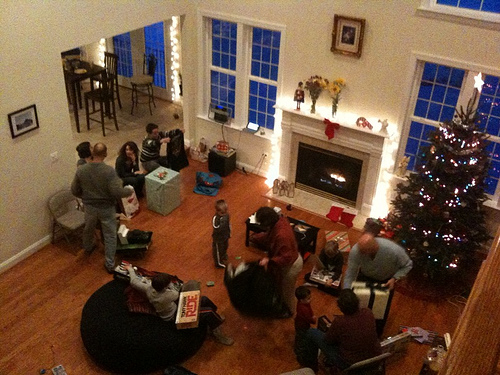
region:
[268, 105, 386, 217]
Fire place with fire lit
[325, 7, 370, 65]
Picture hanging on wall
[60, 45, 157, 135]
Dinning room table with multiple chairs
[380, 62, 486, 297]
Indoor Christmas tree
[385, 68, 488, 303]
Christmas tree with lights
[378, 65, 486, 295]
Christmas tree with lights on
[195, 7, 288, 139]
Indoor window with blue background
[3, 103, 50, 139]
Small picture hanging on the wall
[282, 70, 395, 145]
Flowers on fireplace mantle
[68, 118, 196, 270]
Multiple adults talking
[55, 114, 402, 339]
several people in a living room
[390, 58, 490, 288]
a Christmas tree decorated with lights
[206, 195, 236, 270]
a young boy with gray pajamas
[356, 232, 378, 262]
the head of a bald man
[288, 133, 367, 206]
a fire burning in a fireplace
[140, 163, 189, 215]
a large wrapped box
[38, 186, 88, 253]
a gray folding chair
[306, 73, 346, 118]
two vases full of flowers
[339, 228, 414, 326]
a man holding a wrapped present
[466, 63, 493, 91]
the star on a Christmas tree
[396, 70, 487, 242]
decorated and lit up Christmas tree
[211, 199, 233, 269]
little boy watching a woman cleaning up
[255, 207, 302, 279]
woman wearing a red sweater holding a trash bag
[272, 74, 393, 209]
decorated fireplace with a fire going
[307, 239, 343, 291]
little boy opening a Christmas present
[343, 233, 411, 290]
bald man wearing a gray sweater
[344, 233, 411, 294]
middle-aged man holding a Christmas present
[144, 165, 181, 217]
large Christmas present in baby blue wrapper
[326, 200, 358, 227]
two Christmas stockings by the fireplace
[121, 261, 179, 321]
little boy sitting on a black beanbag chair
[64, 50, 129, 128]
A dining room table set.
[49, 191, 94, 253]
A beige foldable chair.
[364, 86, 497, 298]
A lit up Christmas tree.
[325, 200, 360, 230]
Two red and white Christmas stockings.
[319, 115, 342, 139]
A red bow.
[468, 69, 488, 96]
A star on top of a christmas tree.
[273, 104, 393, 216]
A white fireplace.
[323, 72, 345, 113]
Yellow flowers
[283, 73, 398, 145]
A white fireplace mantle.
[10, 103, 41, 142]
A black framed picture hanging on the wall.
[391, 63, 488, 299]
The decorated Christmas tree covered in lights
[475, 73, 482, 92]
The lighted star on top of the Christmas tree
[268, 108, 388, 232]
The fire place with a fire in it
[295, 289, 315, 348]
A toddler in a red sweatshirt and black pants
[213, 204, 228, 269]
The toddler in a track suit with a white stripe down the side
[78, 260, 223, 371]
A child sitting on the beanbag with his presents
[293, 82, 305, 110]
The nutcracker sitting on top of the fireplace mantle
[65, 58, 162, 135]
A dining room suite in the room to the left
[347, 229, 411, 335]
A bald man with gray shirt handing out gifts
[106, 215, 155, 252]
A baby sitting in a carrier on the left side of the photo